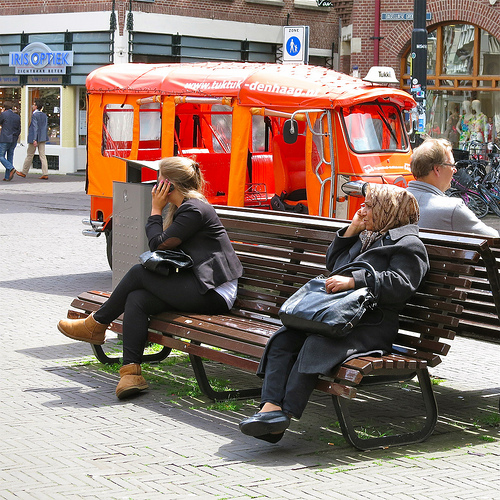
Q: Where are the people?
A: On benches.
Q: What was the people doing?
A: Sitting.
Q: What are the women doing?
A: Talking on phones.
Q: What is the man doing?
A: Watching.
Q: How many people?
A: 3.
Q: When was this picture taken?
A: During the day.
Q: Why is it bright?
A: It's daylight.